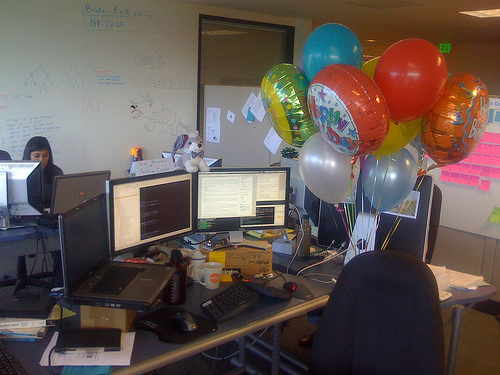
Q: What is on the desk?
A: Computer monitors.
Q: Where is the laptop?
A: On the desk.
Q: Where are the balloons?
A: On the desk.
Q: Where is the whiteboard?
A: On the wall.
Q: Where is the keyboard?
A: On the desk.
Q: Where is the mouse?
A: On the desk.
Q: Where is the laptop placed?
A: Table.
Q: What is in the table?
A: Computer.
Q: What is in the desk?
A: Computer.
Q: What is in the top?
A: Ballons.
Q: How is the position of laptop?
A: Open.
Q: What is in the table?
A: Monitors.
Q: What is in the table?
A: Board.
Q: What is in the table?
A: Chair.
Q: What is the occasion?
A: A birthday.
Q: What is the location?
A: The office.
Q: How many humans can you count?
A: 1.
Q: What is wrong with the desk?
A: It needs to be cleaned.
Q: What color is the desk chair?
A: Black.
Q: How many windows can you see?
A: 1.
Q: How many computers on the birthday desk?
A: 3.